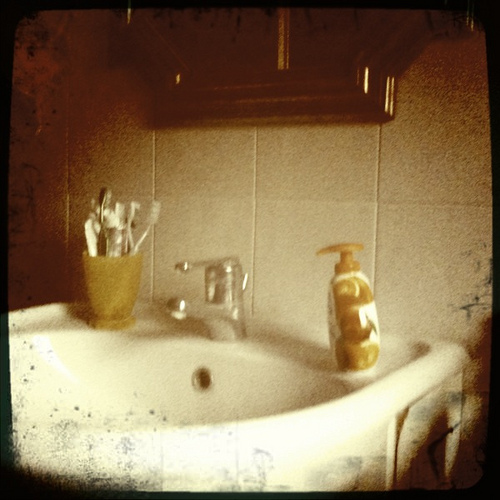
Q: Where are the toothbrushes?
A: In glass on top of sink.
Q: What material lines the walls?
A: Tile.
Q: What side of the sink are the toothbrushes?
A: Left.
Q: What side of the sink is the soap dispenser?
A: The right.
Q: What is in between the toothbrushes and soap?
A: The faucet.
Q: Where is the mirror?
A: Above the sink.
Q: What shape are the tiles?
A: Square.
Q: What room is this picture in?
A: Bathroom.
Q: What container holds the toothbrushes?
A: A cup.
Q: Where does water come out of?
A: The faucet.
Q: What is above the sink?
A: A mirror.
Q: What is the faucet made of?
A: Silver.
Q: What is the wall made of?
A: Tile.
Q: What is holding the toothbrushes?
A: A jar.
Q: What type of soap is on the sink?
A: Hand soap.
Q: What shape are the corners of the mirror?
A: Curved.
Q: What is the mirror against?
A: A tile wall.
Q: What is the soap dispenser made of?
A: Plastic.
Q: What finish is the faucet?
A: Chrome.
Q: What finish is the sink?
A: Procelain.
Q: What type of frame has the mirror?
A: Silver.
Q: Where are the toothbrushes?
A: In a cup.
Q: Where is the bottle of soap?
A: On the sink.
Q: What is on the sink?
A: Soap.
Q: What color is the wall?
A: White.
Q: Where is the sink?
A: On the wall.